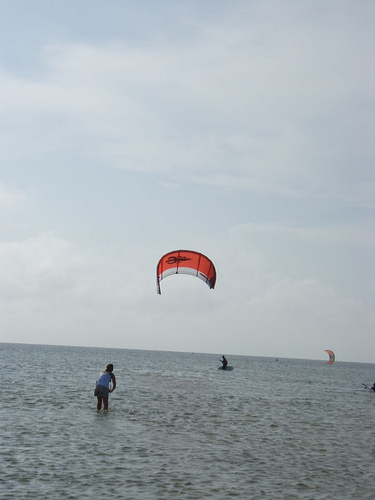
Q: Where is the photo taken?
A: Beach.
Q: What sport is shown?
A: Parasailing.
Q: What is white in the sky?
A: Clouds.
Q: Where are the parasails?
A: In the air.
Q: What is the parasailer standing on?
A: Surfboard.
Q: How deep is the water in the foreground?
A: Knee deep.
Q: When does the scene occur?
A: Daytime.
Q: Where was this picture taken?
A: In the water.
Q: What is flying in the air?
A: A kite.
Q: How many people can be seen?
A: Two.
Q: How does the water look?
A: Calm.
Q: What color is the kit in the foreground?
A: Red.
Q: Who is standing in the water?
A: The person in the foreground.